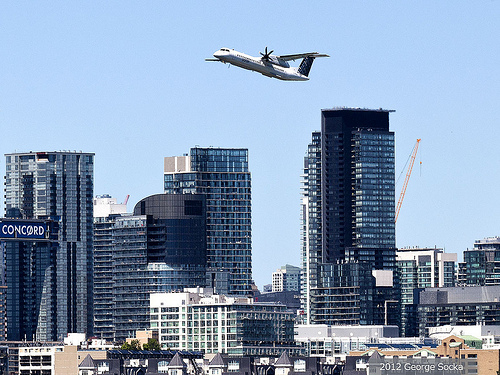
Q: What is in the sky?
A: An airplane.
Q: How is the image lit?
A: Naturally.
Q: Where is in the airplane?
A: In the sky.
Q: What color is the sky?
A: Blue.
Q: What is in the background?
A: Buildings.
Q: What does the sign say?
A: Concord.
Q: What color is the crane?
A: Orange.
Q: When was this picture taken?
A: During the day.